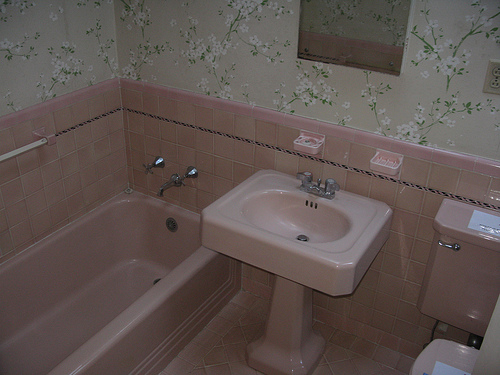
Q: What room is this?
A: Bathroom.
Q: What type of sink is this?
A: Pedestal.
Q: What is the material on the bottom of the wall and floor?
A: Tile.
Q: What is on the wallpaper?
A: Flowers.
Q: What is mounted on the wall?
A: A mirror.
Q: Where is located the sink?
A: In the bathroom.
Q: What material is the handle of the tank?
A: Metal.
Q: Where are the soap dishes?
A: Above the sink.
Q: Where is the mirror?
A: Above the sink.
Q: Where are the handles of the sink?
A: On side the faucet.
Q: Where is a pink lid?
A: Over the tank.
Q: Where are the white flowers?
A: On the wall.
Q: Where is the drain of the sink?
A: Under the faucet.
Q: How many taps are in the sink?
A: Two.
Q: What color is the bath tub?
A: Pink.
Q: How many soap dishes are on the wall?
A: One.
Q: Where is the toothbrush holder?
A: On the wall.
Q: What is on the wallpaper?
A: Flowers.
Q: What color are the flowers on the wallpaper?
A: White.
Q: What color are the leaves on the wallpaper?
A: Green.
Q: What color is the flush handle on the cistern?
A: Silver.